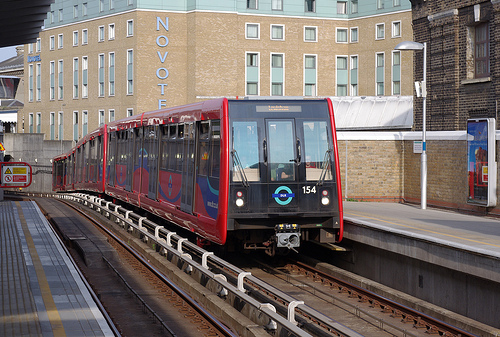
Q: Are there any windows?
A: Yes, there is a window.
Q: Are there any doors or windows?
A: Yes, there is a window.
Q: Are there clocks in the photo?
A: No, there are no clocks.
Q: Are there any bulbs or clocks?
A: No, there are no clocks or bulbs.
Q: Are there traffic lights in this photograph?
A: No, there are no traffic lights.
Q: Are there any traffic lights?
A: No, there are no traffic lights.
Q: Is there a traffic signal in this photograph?
A: No, there are no traffic lights.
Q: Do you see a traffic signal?
A: No, there are no traffic lights.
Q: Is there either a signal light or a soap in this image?
A: No, there are no traffic lights or soaps.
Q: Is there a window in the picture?
A: Yes, there is a window.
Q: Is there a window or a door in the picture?
A: Yes, there is a window.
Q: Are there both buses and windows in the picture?
A: No, there is a window but no buses.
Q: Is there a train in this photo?
A: Yes, there is a train.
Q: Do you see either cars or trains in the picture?
A: Yes, there is a train.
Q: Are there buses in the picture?
A: No, there are no buses.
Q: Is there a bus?
A: No, there are no buses.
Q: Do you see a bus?
A: No, there are no buses.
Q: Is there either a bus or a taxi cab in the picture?
A: No, there are no buses or taxis.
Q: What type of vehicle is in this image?
A: The vehicle is a train.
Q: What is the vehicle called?
A: The vehicle is a train.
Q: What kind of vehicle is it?
A: The vehicle is a train.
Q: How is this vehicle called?
A: That is a train.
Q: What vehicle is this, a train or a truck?
A: That is a train.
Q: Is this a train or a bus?
A: This is a train.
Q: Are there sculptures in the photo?
A: No, there are no sculptures.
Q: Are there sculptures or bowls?
A: No, there are no sculptures or bowls.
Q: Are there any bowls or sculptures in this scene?
A: No, there are no sculptures or bowls.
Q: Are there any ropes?
A: No, there are no ropes.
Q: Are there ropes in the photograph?
A: No, there are no ropes.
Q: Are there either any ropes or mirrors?
A: No, there are no ropes or mirrors.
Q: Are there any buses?
A: No, there are no buses.